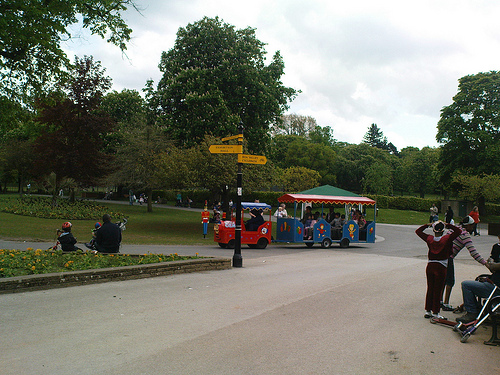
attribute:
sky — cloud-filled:
[20, 0, 497, 154]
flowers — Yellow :
[5, 248, 55, 266]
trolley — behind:
[216, 182, 378, 247]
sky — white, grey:
[331, 15, 392, 66]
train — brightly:
[215, 187, 379, 250]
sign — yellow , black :
[237, 151, 269, 165]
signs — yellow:
[192, 126, 272, 180]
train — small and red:
[216, 202, 269, 247]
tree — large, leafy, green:
[139, 15, 302, 157]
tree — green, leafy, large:
[435, 70, 497, 216]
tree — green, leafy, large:
[359, 120, 394, 152]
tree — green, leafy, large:
[1, 0, 151, 135]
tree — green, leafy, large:
[307, 122, 334, 143]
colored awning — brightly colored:
[275, 184, 377, 204]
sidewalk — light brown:
[198, 283, 422, 369]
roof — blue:
[277, 191, 385, 207]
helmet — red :
[60, 220, 74, 231]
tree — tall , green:
[356, 126, 405, 194]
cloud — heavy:
[298, 55, 355, 107]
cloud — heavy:
[346, 92, 392, 120]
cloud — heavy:
[358, 50, 473, 107]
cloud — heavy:
[80, 23, 176, 95]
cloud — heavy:
[303, 3, 484, 54]